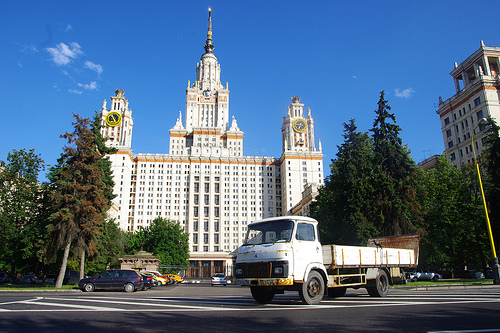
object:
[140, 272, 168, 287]
cars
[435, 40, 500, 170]
building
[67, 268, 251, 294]
parking lot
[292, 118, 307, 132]
clock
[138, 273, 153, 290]
car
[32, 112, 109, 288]
tree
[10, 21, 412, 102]
clouds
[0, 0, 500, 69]
sky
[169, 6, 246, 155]
tower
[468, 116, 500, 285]
light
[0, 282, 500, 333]
ground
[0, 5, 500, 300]
setting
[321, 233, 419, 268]
truck bed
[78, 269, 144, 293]
black car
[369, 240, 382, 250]
bird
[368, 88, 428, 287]
trees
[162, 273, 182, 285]
cars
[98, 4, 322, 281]
building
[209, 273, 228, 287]
car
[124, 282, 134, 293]
tire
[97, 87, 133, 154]
tower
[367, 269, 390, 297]
tire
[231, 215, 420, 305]
truck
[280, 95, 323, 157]
tower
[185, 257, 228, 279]
entrance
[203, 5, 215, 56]
spike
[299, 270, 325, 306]
tire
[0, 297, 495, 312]
lines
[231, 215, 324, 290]
cab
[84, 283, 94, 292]
tire